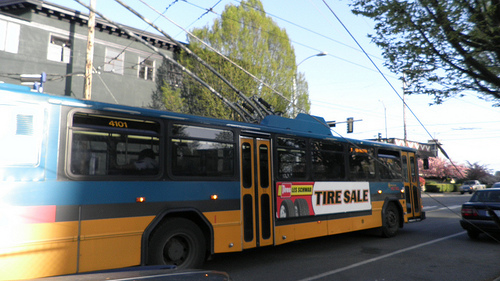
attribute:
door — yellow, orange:
[240, 135, 272, 246]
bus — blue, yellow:
[2, 85, 428, 270]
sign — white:
[273, 180, 375, 218]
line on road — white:
[418, 202, 463, 253]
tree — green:
[351, 0, 499, 106]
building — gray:
[0, 5, 295, 117]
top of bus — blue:
[1, 86, 420, 150]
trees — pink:
[412, 156, 473, 184]